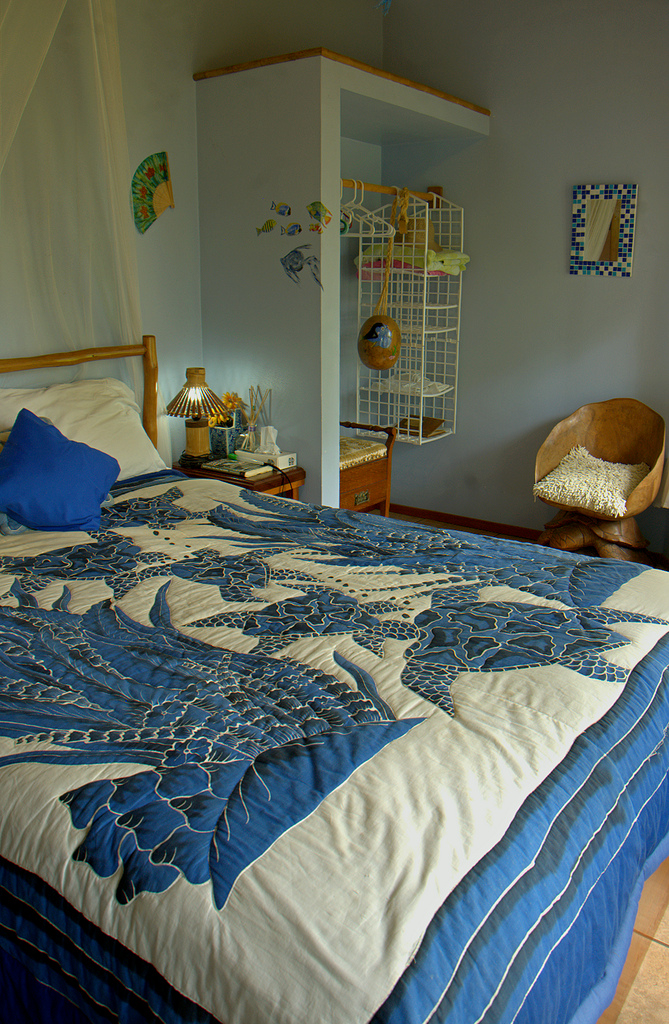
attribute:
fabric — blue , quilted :
[79, 802, 151, 867]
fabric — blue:
[123, 798, 188, 846]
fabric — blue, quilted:
[193, 751, 250, 806]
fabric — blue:
[322, 638, 414, 728]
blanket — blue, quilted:
[0, 459, 668, 1020]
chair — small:
[534, 390, 652, 559]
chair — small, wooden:
[530, 392, 666, 557]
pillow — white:
[536, 438, 662, 517]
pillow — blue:
[1, 402, 110, 535]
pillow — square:
[0, 404, 131, 545]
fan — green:
[132, 145, 192, 235]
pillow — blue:
[6, 409, 122, 536]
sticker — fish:
[245, 184, 331, 294]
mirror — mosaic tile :
[564, 181, 638, 272]